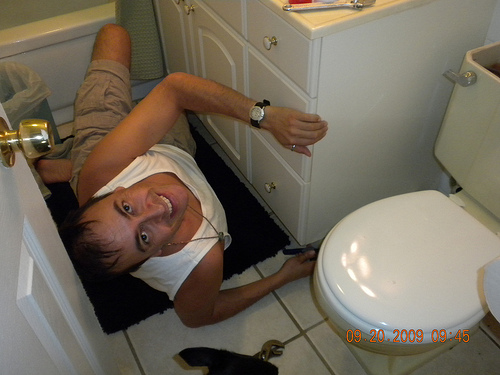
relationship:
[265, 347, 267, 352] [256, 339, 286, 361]
part of a wrench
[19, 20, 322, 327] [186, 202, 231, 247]
he wearing a necklace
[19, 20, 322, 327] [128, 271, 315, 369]
he lying on bathroom floor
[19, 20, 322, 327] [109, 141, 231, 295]
he wearing a tank top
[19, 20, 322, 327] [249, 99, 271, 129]
he with his watch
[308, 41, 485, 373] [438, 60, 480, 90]
toilet with handle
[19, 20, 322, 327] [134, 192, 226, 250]
he with necklace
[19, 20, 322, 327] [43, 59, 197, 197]
he wearing cargo pants